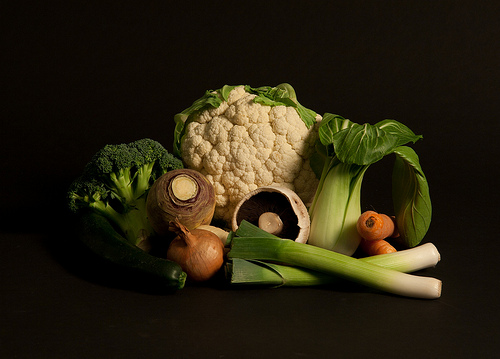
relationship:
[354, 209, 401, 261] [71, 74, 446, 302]
carrots next to greenery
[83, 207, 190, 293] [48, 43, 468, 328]
zucchini in picture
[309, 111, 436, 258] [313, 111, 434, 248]
veggie has long leaves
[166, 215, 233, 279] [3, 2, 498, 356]
vegetable are on a black background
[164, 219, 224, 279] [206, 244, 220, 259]
onion has a reflection of light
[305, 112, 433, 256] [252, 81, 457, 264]
greens are on vegetable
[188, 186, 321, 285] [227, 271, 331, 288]
root has edge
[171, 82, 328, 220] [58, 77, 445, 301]
cauliflower in a group of vegetables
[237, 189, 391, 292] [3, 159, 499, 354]
two leeks are laying on table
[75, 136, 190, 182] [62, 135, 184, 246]
top of broccoli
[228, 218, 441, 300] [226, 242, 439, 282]
celery on top of celery